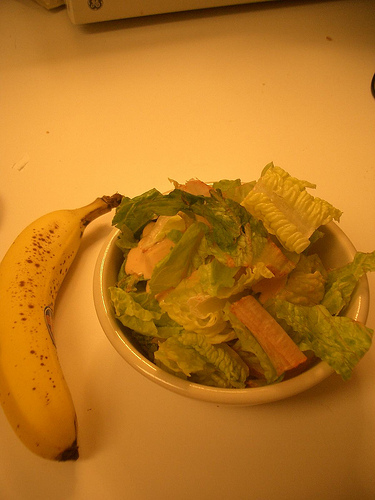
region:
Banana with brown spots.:
[0, 186, 131, 461]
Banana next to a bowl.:
[0, 156, 371, 466]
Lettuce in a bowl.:
[94, 156, 369, 388]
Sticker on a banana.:
[1, 182, 121, 462]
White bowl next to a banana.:
[0, 180, 370, 457]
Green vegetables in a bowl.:
[105, 173, 360, 368]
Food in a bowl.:
[94, 150, 354, 375]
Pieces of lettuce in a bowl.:
[129, 180, 362, 388]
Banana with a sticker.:
[1, 184, 128, 464]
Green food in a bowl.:
[105, 165, 371, 391]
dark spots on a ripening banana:
[15, 205, 76, 299]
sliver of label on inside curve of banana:
[37, 300, 64, 360]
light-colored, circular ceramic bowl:
[80, 152, 368, 412]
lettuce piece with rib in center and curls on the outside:
[237, 154, 342, 259]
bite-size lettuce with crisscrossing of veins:
[292, 300, 363, 378]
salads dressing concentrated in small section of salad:
[120, 210, 195, 288]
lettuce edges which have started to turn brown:
[232, 232, 307, 299]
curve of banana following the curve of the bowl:
[34, 228, 141, 364]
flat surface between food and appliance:
[32, 2, 315, 224]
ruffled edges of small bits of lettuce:
[106, 283, 220, 333]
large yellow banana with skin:
[1, 179, 84, 468]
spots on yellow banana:
[11, 258, 35, 346]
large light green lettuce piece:
[243, 163, 335, 263]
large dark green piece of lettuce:
[118, 188, 242, 234]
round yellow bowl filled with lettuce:
[105, 196, 374, 416]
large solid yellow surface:
[8, 95, 372, 445]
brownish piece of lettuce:
[230, 293, 319, 373]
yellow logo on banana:
[42, 300, 72, 361]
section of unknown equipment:
[76, 0, 309, 20]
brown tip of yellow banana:
[91, 185, 126, 219]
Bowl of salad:
[95, 165, 370, 398]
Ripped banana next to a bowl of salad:
[3, 180, 100, 461]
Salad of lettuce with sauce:
[107, 167, 363, 389]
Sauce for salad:
[120, 206, 193, 276]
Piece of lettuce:
[240, 162, 338, 251]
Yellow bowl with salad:
[85, 175, 371, 403]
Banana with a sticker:
[0, 182, 122, 462]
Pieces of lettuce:
[114, 172, 345, 376]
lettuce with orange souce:
[123, 207, 323, 345]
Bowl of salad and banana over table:
[2, 161, 374, 462]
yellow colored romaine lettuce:
[245, 156, 340, 249]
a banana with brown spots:
[6, 188, 122, 439]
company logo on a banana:
[39, 297, 63, 350]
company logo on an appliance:
[78, 0, 123, 25]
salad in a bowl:
[101, 170, 362, 407]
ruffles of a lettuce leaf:
[245, 163, 328, 250]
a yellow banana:
[5, 180, 105, 460]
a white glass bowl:
[102, 176, 363, 416]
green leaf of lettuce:
[103, 182, 202, 238]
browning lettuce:
[248, 246, 296, 318]